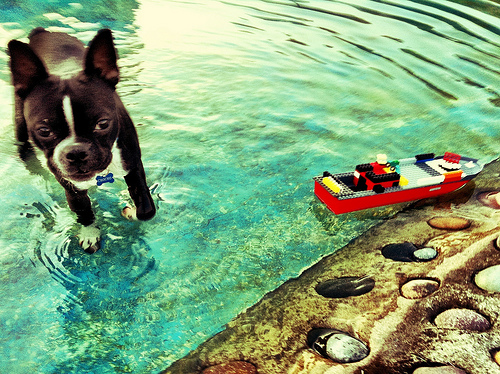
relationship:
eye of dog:
[76, 103, 135, 139] [15, 12, 193, 251]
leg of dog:
[99, 139, 164, 213] [15, 12, 193, 251]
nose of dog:
[65, 145, 97, 172] [15, 12, 193, 251]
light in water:
[199, 37, 254, 76] [190, 20, 349, 189]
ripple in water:
[282, 6, 383, 90] [190, 20, 349, 189]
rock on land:
[298, 234, 409, 317] [326, 224, 458, 322]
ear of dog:
[72, 13, 151, 94] [15, 12, 193, 251]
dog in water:
[15, 12, 193, 251] [190, 20, 349, 189]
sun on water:
[155, 12, 194, 42] [190, 20, 349, 189]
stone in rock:
[386, 250, 431, 276] [298, 234, 409, 317]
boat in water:
[266, 127, 481, 240] [190, 20, 349, 189]